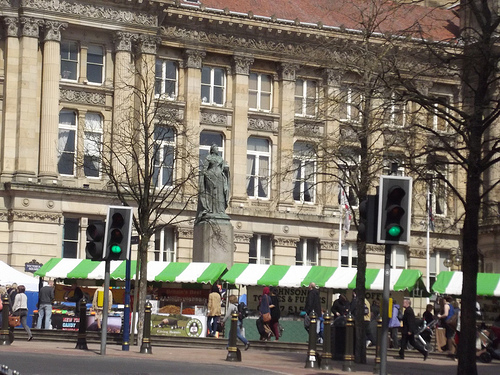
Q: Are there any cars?
A: No, there are no cars.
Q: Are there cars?
A: No, there are no cars.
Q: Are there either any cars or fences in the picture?
A: No, there are no cars or fences.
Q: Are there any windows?
A: Yes, there are windows.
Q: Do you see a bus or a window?
A: Yes, there are windows.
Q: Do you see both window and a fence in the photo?
A: No, there are windows but no fences.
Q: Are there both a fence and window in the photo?
A: No, there are windows but no fences.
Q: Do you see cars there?
A: No, there are no cars.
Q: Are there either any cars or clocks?
A: No, there are no cars or clocks.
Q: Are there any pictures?
A: No, there are no pictures.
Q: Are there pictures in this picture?
A: No, there are no pictures.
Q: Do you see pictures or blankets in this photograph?
A: No, there are no pictures or blankets.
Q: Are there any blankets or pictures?
A: No, there are no pictures or blankets.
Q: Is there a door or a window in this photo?
A: Yes, there is a window.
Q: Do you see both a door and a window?
A: No, there is a window but no doors.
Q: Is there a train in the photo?
A: No, there are no trains.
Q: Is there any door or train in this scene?
A: No, there are no trains or doors.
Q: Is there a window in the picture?
A: Yes, there is a window.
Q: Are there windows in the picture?
A: Yes, there is a window.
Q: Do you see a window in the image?
A: Yes, there is a window.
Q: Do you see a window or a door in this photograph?
A: Yes, there is a window.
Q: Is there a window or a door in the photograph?
A: Yes, there is a window.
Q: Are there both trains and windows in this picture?
A: No, there is a window but no trains.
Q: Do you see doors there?
A: No, there are no doors.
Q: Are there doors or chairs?
A: No, there are no doors or chairs.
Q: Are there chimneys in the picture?
A: No, there are no chimneys.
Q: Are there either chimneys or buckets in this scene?
A: No, there are no chimneys or buckets.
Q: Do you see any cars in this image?
A: No, there are no cars.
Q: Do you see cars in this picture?
A: No, there are no cars.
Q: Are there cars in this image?
A: No, there are no cars.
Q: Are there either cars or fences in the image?
A: No, there are no cars or fences.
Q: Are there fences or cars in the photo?
A: No, there are no cars or fences.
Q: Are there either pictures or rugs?
A: No, there are no pictures or rugs.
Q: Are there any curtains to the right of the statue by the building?
A: Yes, there are curtains to the right of the statue.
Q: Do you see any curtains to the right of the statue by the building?
A: Yes, there are curtains to the right of the statue.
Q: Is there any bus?
A: No, there are no buses.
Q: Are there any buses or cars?
A: No, there are no buses or cars.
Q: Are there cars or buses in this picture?
A: No, there are no buses or cars.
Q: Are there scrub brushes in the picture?
A: No, there are no scrub brushes.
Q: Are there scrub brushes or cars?
A: No, there are no scrub brushes or cars.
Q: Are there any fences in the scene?
A: No, there are no fences.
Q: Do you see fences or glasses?
A: No, there are no fences or glasses.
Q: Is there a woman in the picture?
A: Yes, there is a woman.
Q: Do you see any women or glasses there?
A: Yes, there is a woman.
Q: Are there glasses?
A: No, there are no glasses.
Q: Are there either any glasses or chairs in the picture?
A: No, there are no glasses or chairs.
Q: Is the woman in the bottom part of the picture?
A: Yes, the woman is in the bottom of the image.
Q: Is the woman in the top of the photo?
A: No, the woman is in the bottom of the image.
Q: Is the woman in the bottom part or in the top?
A: The woman is in the bottom of the image.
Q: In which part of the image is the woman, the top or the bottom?
A: The woman is in the bottom of the image.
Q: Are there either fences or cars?
A: No, there are no cars or fences.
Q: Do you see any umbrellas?
A: No, there are no umbrellas.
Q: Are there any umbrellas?
A: No, there are no umbrellas.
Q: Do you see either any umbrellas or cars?
A: No, there are no umbrellas or cars.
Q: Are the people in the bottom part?
A: Yes, the people are in the bottom of the image.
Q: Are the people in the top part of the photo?
A: No, the people are in the bottom of the image.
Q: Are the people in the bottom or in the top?
A: The people are in the bottom of the image.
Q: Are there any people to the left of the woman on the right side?
A: Yes, there are people to the left of the woman.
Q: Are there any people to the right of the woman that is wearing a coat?
A: No, the people are to the left of the woman.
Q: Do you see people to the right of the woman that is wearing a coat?
A: No, the people are to the left of the woman.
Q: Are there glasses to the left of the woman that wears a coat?
A: No, there are people to the left of the woman.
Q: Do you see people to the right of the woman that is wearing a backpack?
A: Yes, there are people to the right of the woman.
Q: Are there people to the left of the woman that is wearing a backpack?
A: No, the people are to the right of the woman.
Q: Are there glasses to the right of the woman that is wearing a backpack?
A: No, there are people to the right of the woman.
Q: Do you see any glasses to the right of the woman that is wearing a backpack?
A: No, there are people to the right of the woman.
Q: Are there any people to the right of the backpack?
A: Yes, there are people to the right of the backpack.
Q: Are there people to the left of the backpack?
A: No, the people are to the right of the backpack.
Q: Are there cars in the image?
A: No, there are no cars.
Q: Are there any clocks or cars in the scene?
A: No, there are no cars or clocks.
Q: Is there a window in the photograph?
A: Yes, there is a window.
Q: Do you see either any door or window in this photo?
A: Yes, there is a window.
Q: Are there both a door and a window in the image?
A: No, there is a window but no doors.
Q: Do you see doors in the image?
A: No, there are no doors.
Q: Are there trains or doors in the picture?
A: No, there are no doors or trains.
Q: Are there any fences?
A: No, there are no fences.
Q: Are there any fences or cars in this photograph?
A: No, there are no fences or cars.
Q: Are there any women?
A: Yes, there is a woman.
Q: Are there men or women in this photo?
A: Yes, there is a woman.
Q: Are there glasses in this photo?
A: No, there are no glasses.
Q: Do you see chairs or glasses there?
A: No, there are no glasses or chairs.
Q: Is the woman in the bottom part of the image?
A: Yes, the woman is in the bottom of the image.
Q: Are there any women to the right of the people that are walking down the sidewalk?
A: Yes, there is a woman to the right of the people.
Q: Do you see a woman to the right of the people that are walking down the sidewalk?
A: Yes, there is a woman to the right of the people.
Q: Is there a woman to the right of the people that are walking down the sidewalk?
A: Yes, there is a woman to the right of the people.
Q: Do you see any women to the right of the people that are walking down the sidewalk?
A: Yes, there is a woman to the right of the people.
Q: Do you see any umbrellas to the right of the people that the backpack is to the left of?
A: No, there is a woman to the right of the people.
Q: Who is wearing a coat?
A: The woman is wearing a coat.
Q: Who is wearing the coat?
A: The woman is wearing a coat.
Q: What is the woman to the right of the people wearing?
A: The woman is wearing a coat.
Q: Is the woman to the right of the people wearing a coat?
A: Yes, the woman is wearing a coat.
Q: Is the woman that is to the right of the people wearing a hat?
A: No, the woman is wearing a coat.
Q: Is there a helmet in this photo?
A: No, there are no helmets.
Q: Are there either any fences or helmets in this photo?
A: No, there are no helmets or fences.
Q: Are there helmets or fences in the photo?
A: No, there are no helmets or fences.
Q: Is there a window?
A: Yes, there is a window.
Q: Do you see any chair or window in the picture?
A: Yes, there is a window.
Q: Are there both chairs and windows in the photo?
A: No, there is a window but no chairs.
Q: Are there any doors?
A: No, there are no doors.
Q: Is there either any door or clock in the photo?
A: No, there are no doors or clocks.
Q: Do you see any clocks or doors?
A: No, there are no doors or clocks.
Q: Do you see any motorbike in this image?
A: No, there are no motorcycles.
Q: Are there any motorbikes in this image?
A: No, there are no motorbikes.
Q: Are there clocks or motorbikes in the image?
A: No, there are no motorbikes or clocks.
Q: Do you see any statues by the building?
A: Yes, there is a statue by the building.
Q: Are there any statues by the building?
A: Yes, there is a statue by the building.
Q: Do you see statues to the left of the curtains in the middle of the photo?
A: Yes, there is a statue to the left of the curtains.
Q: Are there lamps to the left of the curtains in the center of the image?
A: No, there is a statue to the left of the curtains.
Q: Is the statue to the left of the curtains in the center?
A: Yes, the statue is to the left of the curtains.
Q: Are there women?
A: Yes, there is a woman.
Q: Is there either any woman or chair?
A: Yes, there is a woman.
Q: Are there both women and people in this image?
A: Yes, there are both a woman and a person.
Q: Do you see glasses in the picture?
A: No, there are no glasses.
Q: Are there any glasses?
A: No, there are no glasses.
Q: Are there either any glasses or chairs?
A: No, there are no glasses or chairs.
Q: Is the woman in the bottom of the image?
A: Yes, the woman is in the bottom of the image.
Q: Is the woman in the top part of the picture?
A: No, the woman is in the bottom of the image.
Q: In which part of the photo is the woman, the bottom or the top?
A: The woman is in the bottom of the image.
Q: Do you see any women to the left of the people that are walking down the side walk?
A: Yes, there is a woman to the left of the people.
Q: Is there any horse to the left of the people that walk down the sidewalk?
A: No, there is a woman to the left of the people.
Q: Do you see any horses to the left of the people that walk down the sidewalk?
A: No, there is a woman to the left of the people.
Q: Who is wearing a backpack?
A: The woman is wearing a backpack.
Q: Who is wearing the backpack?
A: The woman is wearing a backpack.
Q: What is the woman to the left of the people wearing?
A: The woman is wearing a backpack.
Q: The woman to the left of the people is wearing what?
A: The woman is wearing a backpack.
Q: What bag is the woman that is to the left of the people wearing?
A: The woman is wearing a backpack.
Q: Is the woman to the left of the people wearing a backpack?
A: Yes, the woman is wearing a backpack.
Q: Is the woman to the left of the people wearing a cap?
A: No, the woman is wearing a backpack.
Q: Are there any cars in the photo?
A: No, there are no cars.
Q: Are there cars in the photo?
A: No, there are no cars.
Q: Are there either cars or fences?
A: No, there are no cars or fences.